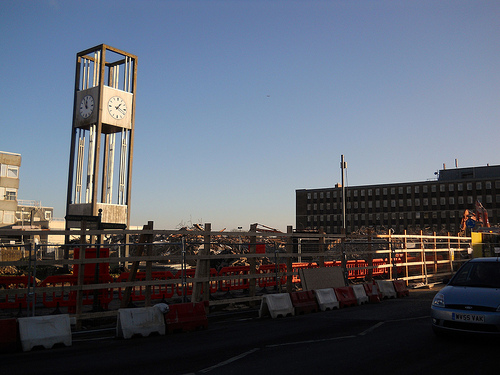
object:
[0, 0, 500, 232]
blue sky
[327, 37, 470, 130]
elephant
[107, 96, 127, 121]
clock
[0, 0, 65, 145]
cloud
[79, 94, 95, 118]
clock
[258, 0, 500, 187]
clouds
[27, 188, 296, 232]
cloud